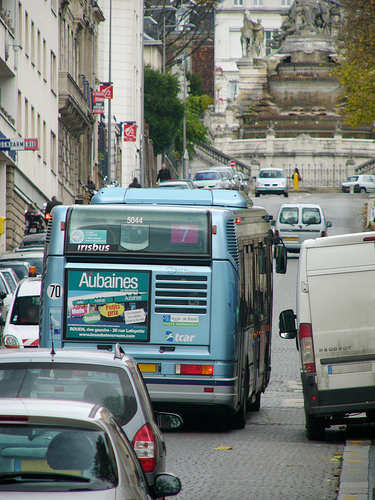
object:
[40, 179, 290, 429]
bus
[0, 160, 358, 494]
traffic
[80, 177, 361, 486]
street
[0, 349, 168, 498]
two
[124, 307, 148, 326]
sign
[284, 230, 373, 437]
car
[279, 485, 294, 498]
cobble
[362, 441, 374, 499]
edge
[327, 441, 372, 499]
sidewalk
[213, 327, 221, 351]
blue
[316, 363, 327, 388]
dirt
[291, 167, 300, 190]
hydrant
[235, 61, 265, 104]
base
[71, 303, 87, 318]
black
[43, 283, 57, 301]
white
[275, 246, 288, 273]
mirror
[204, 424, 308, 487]
part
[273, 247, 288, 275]
side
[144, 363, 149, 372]
part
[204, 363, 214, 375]
indicator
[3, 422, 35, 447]
rear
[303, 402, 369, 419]
bottom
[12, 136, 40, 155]
part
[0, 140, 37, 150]
banner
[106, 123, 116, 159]
part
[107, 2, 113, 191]
post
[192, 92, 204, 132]
part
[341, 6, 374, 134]
tree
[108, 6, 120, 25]
lamp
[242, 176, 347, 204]
end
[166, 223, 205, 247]
route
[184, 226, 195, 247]
seven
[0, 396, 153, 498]
automobile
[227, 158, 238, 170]
do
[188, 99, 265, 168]
stairway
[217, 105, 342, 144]
fountain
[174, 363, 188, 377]
light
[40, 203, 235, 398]
back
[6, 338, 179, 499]
silver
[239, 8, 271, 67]
large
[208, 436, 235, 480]
gray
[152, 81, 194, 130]
green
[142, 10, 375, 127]
behind